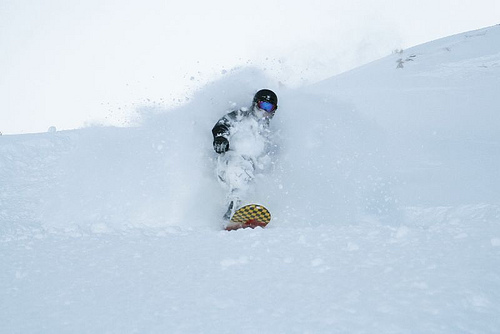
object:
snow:
[359, 250, 411, 279]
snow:
[0, 240, 23, 267]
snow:
[11, 242, 52, 269]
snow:
[144, 240, 174, 267]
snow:
[450, 215, 480, 240]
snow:
[23, 165, 98, 195]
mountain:
[355, 31, 498, 138]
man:
[211, 89, 278, 221]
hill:
[1, 0, 498, 332]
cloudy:
[73, 12, 217, 37]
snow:
[0, 250, 51, 334]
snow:
[356, 77, 427, 154]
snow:
[201, 87, 270, 120]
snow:
[327, 299, 405, 334]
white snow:
[339, 47, 500, 132]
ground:
[383, 174, 408, 218]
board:
[229, 203, 271, 227]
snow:
[151, 179, 208, 219]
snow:
[462, 23, 496, 45]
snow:
[430, 105, 494, 167]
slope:
[440, 196, 500, 334]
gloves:
[212, 135, 229, 153]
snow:
[0, 137, 72, 175]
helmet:
[252, 88, 278, 112]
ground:
[431, 24, 496, 106]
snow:
[143, 106, 192, 137]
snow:
[383, 252, 497, 333]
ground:
[0, 289, 161, 333]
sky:
[1, 2, 500, 131]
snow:
[302, 142, 332, 202]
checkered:
[242, 214, 259, 220]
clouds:
[79, 27, 233, 91]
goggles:
[252, 99, 278, 114]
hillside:
[80, 121, 210, 281]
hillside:
[362, 125, 500, 272]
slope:
[0, 279, 352, 334]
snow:
[22, 133, 75, 165]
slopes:
[396, 29, 497, 102]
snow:
[129, 156, 195, 205]